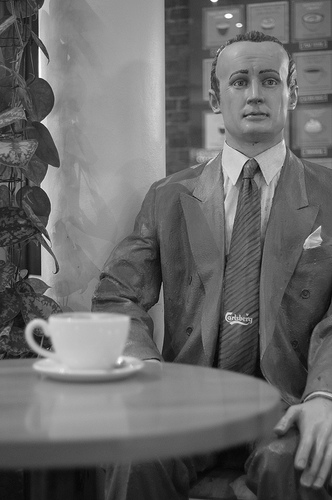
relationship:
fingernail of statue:
[295, 457, 304, 467] [82, 35, 330, 497]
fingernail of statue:
[272, 423, 281, 433] [82, 35, 330, 497]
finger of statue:
[272, 402, 299, 436] [82, 35, 330, 497]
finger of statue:
[293, 431, 317, 472] [82, 35, 330, 497]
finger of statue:
[295, 431, 309, 472] [82, 35, 330, 497]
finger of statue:
[300, 436, 320, 489] [82, 35, 330, 497]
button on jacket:
[185, 273, 192, 283] [98, 149, 328, 424]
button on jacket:
[297, 286, 311, 301] [98, 149, 328, 424]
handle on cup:
[25, 319, 56, 360] [27, 307, 132, 364]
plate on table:
[39, 352, 154, 377] [2, 350, 268, 477]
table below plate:
[4, 361, 283, 484] [31, 352, 143, 380]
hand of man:
[273, 399, 329, 485] [91, 30, 332, 409]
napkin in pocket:
[300, 220, 325, 257] [293, 228, 330, 279]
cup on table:
[23, 308, 130, 373] [0, 324, 285, 474]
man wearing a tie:
[91, 30, 332, 409] [213, 158, 270, 376]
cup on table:
[23, 308, 130, 373] [5, 347, 271, 499]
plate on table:
[31, 352, 142, 385] [5, 347, 271, 499]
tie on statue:
[219, 157, 262, 375] [82, 35, 330, 497]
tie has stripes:
[219, 157, 262, 375] [233, 257, 249, 345]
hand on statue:
[273, 394, 332, 490] [82, 35, 330, 497]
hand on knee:
[273, 394, 332, 490] [249, 424, 316, 489]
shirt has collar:
[206, 124, 303, 268] [209, 135, 296, 181]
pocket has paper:
[298, 221, 320, 257] [302, 215, 320, 263]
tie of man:
[219, 157, 262, 375] [82, 14, 331, 493]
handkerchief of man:
[300, 226, 320, 243] [82, 14, 331, 493]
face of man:
[219, 43, 291, 137] [91, 30, 332, 409]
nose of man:
[247, 81, 267, 106] [83, 23, 331, 415]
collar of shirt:
[217, 138, 293, 183] [202, 134, 284, 304]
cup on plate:
[21, 305, 143, 374] [31, 352, 143, 380]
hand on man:
[273, 399, 329, 485] [82, 14, 331, 493]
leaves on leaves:
[1, 0, 64, 359] [1, 0, 61, 361]